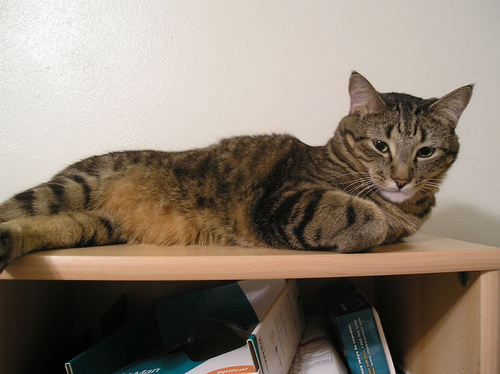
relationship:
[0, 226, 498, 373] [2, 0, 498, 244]
shelf in front of wall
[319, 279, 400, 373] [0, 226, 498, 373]
box on shelf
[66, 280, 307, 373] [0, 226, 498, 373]
box on shelf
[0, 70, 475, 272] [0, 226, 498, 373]
cat on shelf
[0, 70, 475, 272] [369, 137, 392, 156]
cat has an eye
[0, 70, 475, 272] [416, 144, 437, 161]
cat has an eye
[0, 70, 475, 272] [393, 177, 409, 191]
cat has a nose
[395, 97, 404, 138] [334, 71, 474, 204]
stripes are on head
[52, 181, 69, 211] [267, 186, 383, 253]
stripes are on leg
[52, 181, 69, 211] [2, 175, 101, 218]
stripes are on leg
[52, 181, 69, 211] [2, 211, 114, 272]
stripes are on leg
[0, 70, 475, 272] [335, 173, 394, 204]
cat has whiskers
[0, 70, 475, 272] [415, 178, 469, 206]
cat has whiskers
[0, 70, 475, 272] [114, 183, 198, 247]
cat has a tummy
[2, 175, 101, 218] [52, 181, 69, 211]
leg has stripes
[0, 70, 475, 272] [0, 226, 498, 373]
cat sitting on shelf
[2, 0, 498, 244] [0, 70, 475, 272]
wall behind cat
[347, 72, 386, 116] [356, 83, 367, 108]
ear has hair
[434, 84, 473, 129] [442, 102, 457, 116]
ear has hair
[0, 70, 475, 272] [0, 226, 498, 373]
cat laying on shelf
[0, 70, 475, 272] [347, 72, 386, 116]
cat has an ear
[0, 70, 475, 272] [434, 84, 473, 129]
cat has an ear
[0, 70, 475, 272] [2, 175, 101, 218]
cat has a leg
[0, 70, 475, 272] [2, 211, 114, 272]
cat has a leg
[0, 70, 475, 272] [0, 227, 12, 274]
cat has a paw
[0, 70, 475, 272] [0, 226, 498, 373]
cat lying down on shelf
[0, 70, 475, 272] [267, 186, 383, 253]
cat has a leg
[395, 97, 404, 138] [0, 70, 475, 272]
stripes are on cat